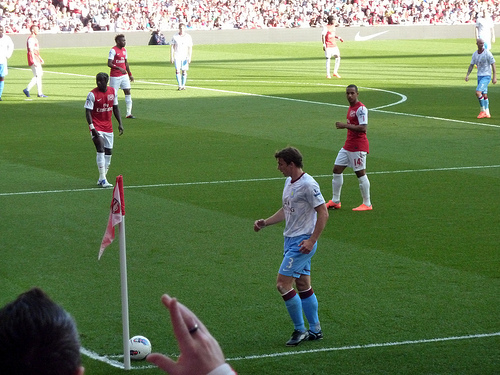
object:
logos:
[132, 339, 152, 349]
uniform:
[474, 57, 493, 93]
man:
[466, 36, 500, 123]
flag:
[97, 172, 139, 370]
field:
[38, 225, 90, 263]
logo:
[351, 28, 402, 42]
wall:
[265, 25, 486, 47]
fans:
[233, 1, 430, 28]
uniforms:
[85, 70, 121, 189]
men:
[25, 27, 137, 186]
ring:
[186, 325, 206, 336]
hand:
[145, 292, 233, 372]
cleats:
[352, 202, 374, 210]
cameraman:
[0, 286, 237, 373]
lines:
[237, 90, 447, 124]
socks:
[284, 294, 304, 328]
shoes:
[474, 111, 494, 122]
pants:
[476, 78, 493, 97]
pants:
[110, 74, 133, 88]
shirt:
[281, 176, 325, 238]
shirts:
[83, 86, 118, 132]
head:
[1, 286, 82, 373]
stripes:
[128, 163, 495, 188]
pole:
[117, 229, 131, 369]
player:
[252, 145, 328, 335]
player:
[325, 83, 373, 212]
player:
[82, 67, 123, 188]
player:
[320, 13, 343, 80]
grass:
[147, 106, 320, 176]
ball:
[129, 335, 152, 360]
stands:
[34, 24, 466, 48]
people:
[25, 24, 487, 230]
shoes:
[284, 321, 309, 348]